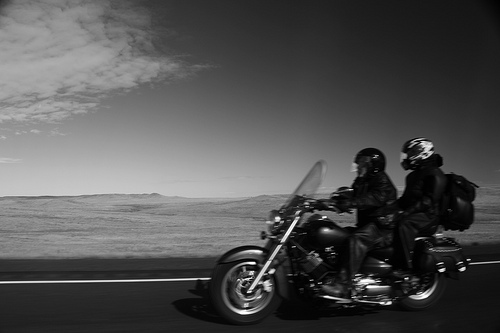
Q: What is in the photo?
A: A motorbike.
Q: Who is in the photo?
A: People.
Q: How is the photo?
A: Clear.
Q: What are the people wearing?
A: Clothes.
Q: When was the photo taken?
A: Daytime.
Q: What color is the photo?
A: Black.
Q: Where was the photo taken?
A: On the road.